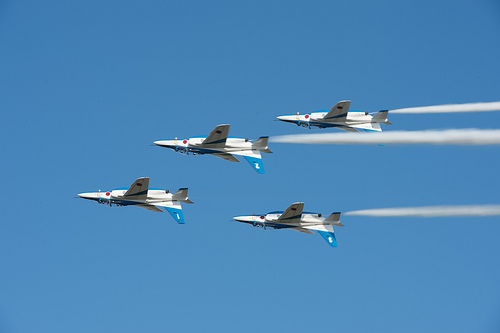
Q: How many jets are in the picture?
A: 4.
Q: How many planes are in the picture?
A: 4.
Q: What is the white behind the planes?
A: Smoke.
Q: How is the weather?
A: Clear.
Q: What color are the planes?
A: White and blue.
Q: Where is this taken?
A: At a air show.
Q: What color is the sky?
A: Blue.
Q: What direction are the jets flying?
A: West.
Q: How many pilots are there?
A: 4.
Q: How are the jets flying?
A: Upside down.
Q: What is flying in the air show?
A: The jets.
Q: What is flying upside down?
A: The planes.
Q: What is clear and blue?
A: The sky.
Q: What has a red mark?
A: The planes.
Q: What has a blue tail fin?
A: The planes.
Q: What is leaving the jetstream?
A: The planes.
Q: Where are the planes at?
A: At an airshow.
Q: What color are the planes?
A: White.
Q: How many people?
A: Four.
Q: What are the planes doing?
A: Flying in formation.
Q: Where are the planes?
A: In the sky.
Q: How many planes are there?
A: 4.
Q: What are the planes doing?
A: Flying.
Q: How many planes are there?
A: Four.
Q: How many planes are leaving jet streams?
A: Three.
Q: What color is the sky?
A: Blue.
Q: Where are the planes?
A: In the sky.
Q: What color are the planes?
A: White.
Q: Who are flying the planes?
A: Pilots.